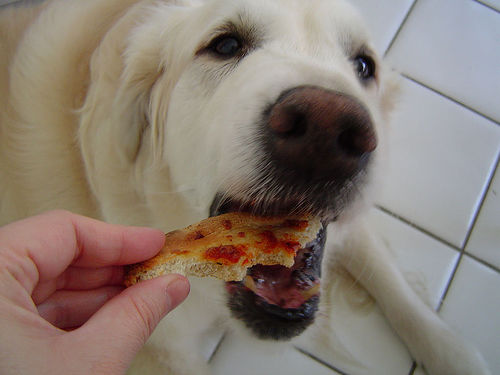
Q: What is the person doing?
A: Feeding the dog.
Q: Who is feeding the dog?
A: A person.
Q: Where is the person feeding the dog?
A: In the kitchen.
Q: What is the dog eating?
A: Pizza.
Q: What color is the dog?
A: White.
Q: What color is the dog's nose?
A: Brown.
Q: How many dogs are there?
A: One.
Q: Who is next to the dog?
A: Noone.